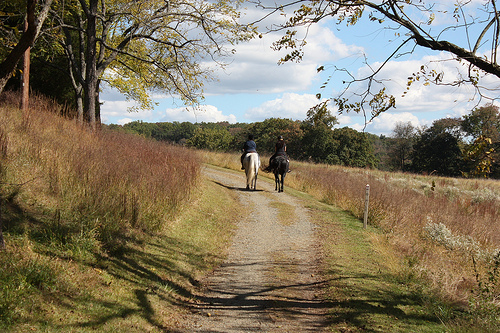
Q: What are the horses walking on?
A: The trail.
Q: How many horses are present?
A: Two.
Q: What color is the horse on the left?
A: White.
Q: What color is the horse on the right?
A: Black.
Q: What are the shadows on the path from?
A: The trees.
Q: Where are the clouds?
A: In the sky.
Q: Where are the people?
A: On the horses.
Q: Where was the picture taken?
A: Along the trail.